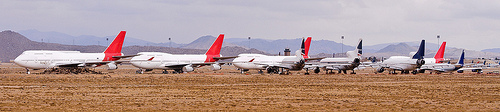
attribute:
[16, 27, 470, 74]
airplanes — red, white, blue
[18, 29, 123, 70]
airplane — white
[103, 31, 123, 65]
tail — red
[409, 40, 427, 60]
tail — blue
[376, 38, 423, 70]
airplane — white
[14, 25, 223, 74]
planes — red, white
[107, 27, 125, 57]
tail — red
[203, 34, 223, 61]
tail — red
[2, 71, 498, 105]
ground — brown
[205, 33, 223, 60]
tail — dark red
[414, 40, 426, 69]
tail — dark blue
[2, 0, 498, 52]
sky —  blue, cloudy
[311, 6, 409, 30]
clouds — white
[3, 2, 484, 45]
sky — blue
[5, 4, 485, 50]
sky — blue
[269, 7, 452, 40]
clouds — white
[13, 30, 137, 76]
plane — white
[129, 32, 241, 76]
plane — white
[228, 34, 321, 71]
plane — white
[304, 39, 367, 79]
plane — white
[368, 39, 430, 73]
plane — white